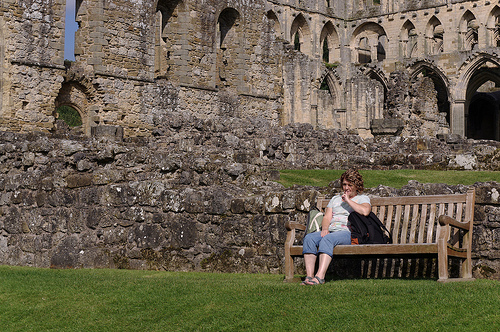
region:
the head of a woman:
[333, 165, 375, 205]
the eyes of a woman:
[328, 168, 375, 202]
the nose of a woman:
[333, 172, 371, 195]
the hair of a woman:
[321, 144, 398, 208]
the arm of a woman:
[316, 198, 335, 233]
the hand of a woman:
[330, 180, 365, 205]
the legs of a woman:
[285, 227, 377, 279]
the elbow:
[338, 197, 376, 216]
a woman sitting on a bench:
[272, 163, 419, 301]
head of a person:
[335, 172, 369, 197]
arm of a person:
[337, 194, 377, 214]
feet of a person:
[294, 270, 326, 290]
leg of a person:
[298, 236, 345, 273]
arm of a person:
[319, 199, 336, 239]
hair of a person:
[343, 166, 370, 188]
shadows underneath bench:
[332, 252, 436, 277]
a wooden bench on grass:
[260, 176, 481, 293]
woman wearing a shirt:
[303, 160, 382, 240]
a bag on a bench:
[342, 200, 399, 251]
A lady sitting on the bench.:
[281, 166, 391, 266]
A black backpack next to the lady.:
[345, 205, 390, 241]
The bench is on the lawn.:
[290, 200, 471, 285]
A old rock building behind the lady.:
[111, 10, 461, 160]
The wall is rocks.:
[55, 146, 226, 251]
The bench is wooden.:
[254, 180, 479, 277]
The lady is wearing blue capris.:
[304, 228, 377, 254]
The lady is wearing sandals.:
[294, 261, 328, 289]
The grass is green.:
[34, 265, 296, 327]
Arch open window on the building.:
[366, 15, 498, 50]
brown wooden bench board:
[454, 199, 461, 246]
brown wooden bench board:
[445, 200, 455, 217]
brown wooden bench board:
[435, 203, 445, 244]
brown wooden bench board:
[423, 200, 435, 244]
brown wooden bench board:
[417, 204, 425, 240]